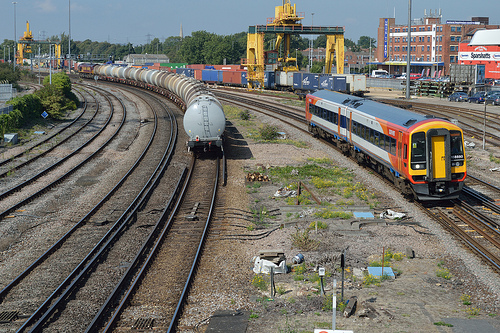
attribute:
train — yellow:
[289, 89, 471, 210]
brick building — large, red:
[366, 12, 491, 84]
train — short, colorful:
[292, 81, 477, 231]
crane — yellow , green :
[219, 5, 377, 78]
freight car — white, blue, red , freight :
[289, 70, 344, 95]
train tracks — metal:
[117, 182, 220, 332]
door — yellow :
[432, 139, 447, 182]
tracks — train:
[89, 177, 224, 309]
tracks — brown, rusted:
[216, 88, 498, 280]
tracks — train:
[437, 198, 499, 264]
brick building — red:
[377, 11, 497, 83]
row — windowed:
[306, 101, 398, 156]